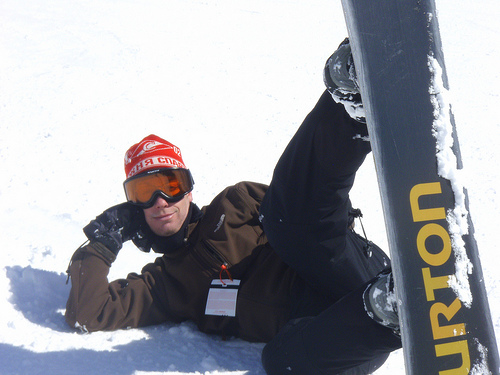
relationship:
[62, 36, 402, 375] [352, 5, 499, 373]
man has board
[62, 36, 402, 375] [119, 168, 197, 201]
man has goggles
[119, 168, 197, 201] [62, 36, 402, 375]
goggles on man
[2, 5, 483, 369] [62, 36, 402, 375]
snow under man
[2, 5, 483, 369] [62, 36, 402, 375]
snow below man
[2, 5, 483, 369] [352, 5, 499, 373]
snow below board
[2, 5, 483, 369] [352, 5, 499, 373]
snow under board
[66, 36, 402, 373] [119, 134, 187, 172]
man wearing beanie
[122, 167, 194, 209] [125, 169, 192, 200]
goggles framing lens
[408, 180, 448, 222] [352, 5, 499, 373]
letter painted on board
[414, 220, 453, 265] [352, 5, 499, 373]
letter painted on board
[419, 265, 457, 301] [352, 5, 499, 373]
letter painted on board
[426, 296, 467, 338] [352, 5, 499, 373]
letter painted on board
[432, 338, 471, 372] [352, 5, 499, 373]
letter painted on board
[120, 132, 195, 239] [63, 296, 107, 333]
head resting on elbow